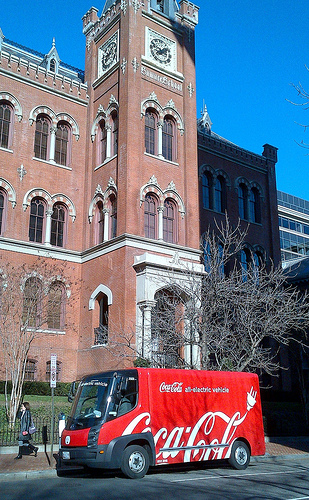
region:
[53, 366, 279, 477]
a van on the side of street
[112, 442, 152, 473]
front tire on van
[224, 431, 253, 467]
rear tire on van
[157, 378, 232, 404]
lettering on the van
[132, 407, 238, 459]
larger lettering on the van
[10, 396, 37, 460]
woman walking on sidewalk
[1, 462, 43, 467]
sidewalk for pedestrians to walk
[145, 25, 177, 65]
clock on side of tower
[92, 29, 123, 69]
clock on opposite side of tower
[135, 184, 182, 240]
arched windows on building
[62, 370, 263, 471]
a red van parked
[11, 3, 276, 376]
a red brick building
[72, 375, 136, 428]
the window of a van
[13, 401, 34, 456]
a woman walking on a side walk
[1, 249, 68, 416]
a bare tree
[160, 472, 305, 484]
a white strip on a road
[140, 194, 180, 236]
windows in the building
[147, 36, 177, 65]
a clock on the building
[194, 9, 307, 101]
a clear blue sky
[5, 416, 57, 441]
a iron fence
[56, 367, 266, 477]
the red van parked on the road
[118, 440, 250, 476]
the wheels on the bus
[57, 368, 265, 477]
the red paint on the van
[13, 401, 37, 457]
the woman walking on the sidewalk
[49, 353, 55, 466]
the pole and sign next to the van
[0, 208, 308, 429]
the bare trees in front of the building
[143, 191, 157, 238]
the window on the building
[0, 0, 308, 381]
the buildings behind the parked van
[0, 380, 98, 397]
the hedge bushes in front of the buiding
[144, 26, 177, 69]
the clock on the tower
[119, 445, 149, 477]
A front wheel on a van.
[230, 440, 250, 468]
A rear wheel of a van.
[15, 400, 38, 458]
A person on a sidewalk.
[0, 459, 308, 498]
A paved road.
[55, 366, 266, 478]
A red vehicle on a road.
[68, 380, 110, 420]
A front window on a vehicle.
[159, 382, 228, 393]
A sign on the body of a vehicle.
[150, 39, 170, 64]
A clock on a building.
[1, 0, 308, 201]
A blue sunny sky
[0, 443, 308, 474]
A sidewalk.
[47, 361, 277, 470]
a coca cola truck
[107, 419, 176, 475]
the front wheel of a truck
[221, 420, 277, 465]
the black wheel of a truck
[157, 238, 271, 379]
a tree with no leaves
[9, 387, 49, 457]
a woman walking down the street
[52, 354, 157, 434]
the windshield on a truck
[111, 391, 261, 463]
big coca cola letters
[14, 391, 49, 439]
a woman with a grey jacket on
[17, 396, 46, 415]
the head of a woman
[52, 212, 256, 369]
a big building in the back ground